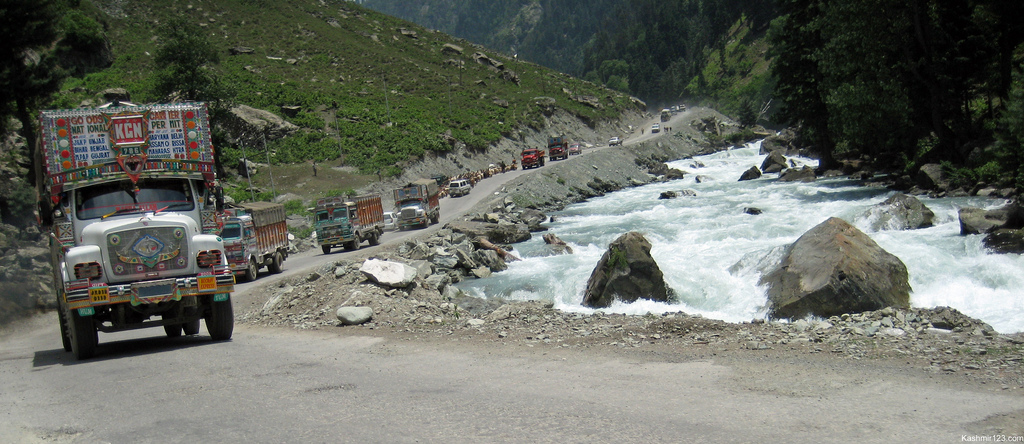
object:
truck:
[16, 91, 262, 363]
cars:
[302, 188, 390, 257]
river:
[432, 128, 1024, 339]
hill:
[0, 0, 660, 269]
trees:
[0, 0, 128, 234]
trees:
[129, 16, 271, 221]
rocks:
[508, 207, 554, 226]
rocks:
[710, 214, 924, 325]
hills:
[584, 0, 1024, 192]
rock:
[345, 253, 425, 289]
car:
[16, 95, 248, 364]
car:
[216, 192, 298, 284]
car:
[388, 175, 443, 232]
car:
[443, 177, 478, 199]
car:
[647, 123, 663, 135]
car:
[515, 145, 548, 170]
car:
[567, 141, 584, 157]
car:
[605, 133, 629, 149]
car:
[659, 106, 676, 122]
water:
[444, 88, 1024, 335]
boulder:
[718, 213, 907, 325]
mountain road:
[0, 101, 1016, 444]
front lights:
[61, 258, 118, 281]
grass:
[0, 0, 655, 190]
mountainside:
[0, 0, 633, 287]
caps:
[736, 205, 771, 218]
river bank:
[350, 95, 1024, 403]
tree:
[737, 0, 1024, 195]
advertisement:
[39, 96, 215, 192]